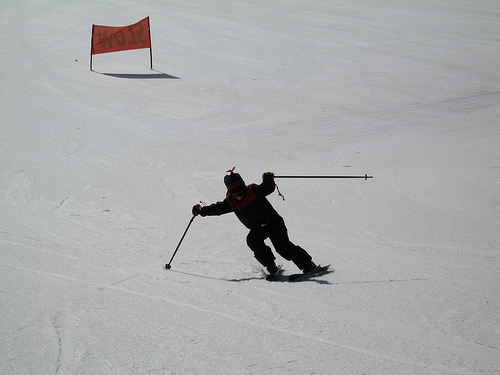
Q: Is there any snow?
A: Yes, there is snow.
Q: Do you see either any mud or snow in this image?
A: Yes, there is snow.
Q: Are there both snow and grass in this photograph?
A: No, there is snow but no grass.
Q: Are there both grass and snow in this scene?
A: No, there is snow but no grass.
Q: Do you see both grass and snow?
A: No, there is snow but no grass.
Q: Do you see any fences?
A: No, there are no fences.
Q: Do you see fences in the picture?
A: No, there are no fences.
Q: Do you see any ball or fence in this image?
A: No, there are no fences or balls.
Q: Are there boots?
A: Yes, there are boots.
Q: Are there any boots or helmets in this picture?
A: Yes, there are boots.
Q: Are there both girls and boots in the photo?
A: No, there are boots but no girls.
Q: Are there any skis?
A: Yes, there are skis.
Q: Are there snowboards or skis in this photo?
A: Yes, there are skis.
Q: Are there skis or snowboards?
A: Yes, there are skis.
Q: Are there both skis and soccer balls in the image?
A: No, there are skis but no soccer balls.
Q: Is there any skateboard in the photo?
A: No, there are no skateboards.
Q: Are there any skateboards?
A: No, there are no skateboards.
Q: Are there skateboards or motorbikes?
A: No, there are no skateboards or motorbikes.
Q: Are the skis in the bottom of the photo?
A: Yes, the skis are in the bottom of the image.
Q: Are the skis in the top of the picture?
A: No, the skis are in the bottom of the image.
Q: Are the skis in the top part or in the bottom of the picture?
A: The skis are in the bottom of the image.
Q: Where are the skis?
A: The skis are in the snow.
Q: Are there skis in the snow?
A: Yes, there are skis in the snow.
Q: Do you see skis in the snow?
A: Yes, there are skis in the snow.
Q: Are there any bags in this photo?
A: No, there are no bags.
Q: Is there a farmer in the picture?
A: No, there are no farmers.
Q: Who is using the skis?
A: The skier is using the skis.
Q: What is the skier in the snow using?
A: The skier is using skis.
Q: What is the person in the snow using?
A: The skier is using skis.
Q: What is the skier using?
A: The skier is using skis.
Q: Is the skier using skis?
A: Yes, the skier is using skis.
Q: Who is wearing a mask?
A: The skier is wearing a mask.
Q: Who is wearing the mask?
A: The skier is wearing a mask.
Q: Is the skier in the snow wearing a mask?
A: Yes, the skier is wearing a mask.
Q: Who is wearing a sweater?
A: The skier is wearing a sweater.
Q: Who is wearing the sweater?
A: The skier is wearing a sweater.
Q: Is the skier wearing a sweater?
A: Yes, the skier is wearing a sweater.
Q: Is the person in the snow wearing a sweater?
A: Yes, the skier is wearing a sweater.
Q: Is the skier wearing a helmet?
A: No, the skier is wearing a sweater.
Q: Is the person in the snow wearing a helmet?
A: No, the skier is wearing a sweater.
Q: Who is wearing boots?
A: The skier is wearing boots.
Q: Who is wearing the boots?
A: The skier is wearing boots.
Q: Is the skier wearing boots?
A: Yes, the skier is wearing boots.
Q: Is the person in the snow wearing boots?
A: Yes, the skier is wearing boots.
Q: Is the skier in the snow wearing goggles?
A: No, the skier is wearing boots.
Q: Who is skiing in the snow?
A: The skier is skiing in the snow.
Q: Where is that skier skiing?
A: The skier is skiing in the snow.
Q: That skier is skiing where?
A: The skier is skiing in the snow.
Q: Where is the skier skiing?
A: The skier is skiing in the snow.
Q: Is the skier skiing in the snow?
A: Yes, the skier is skiing in the snow.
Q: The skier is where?
A: The skier is in the snow.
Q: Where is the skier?
A: The skier is in the snow.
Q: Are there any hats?
A: Yes, there is a hat.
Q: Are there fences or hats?
A: Yes, there is a hat.